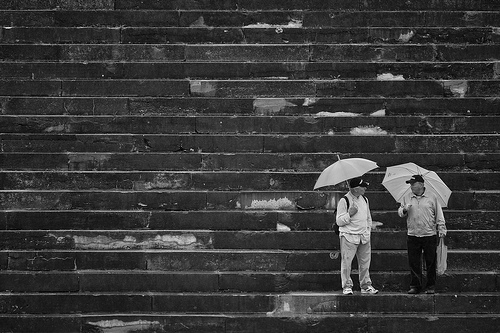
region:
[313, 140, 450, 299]
two old people with umbrellas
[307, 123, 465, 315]
two old people with umbrellas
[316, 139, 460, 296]
two men talking on stairs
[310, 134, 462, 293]
two men holding white umbrellas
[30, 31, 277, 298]
long concrete staircase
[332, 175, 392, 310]
man wearing tennis shoes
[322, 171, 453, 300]
two men wearing ball caps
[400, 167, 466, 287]
man is carrying grocery sack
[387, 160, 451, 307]
man wearing black pants and jacket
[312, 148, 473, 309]
men holding matching white umbrellas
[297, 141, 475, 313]
two men talking in the rain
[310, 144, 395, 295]
man wearing a backpack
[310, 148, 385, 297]
Man with blue jeans holdin umbrella.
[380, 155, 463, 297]
Man holding bag holding umbrella.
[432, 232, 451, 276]
Shopping bag in left hand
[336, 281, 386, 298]
White sneakers on man to left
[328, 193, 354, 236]
backpack on man to the left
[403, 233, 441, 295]
black pants on man to the right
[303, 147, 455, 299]
Men talking to each other with umbrellas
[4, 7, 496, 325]
Weathered flight of long steps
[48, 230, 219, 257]
Worn down step that lost some paint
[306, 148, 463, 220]
Lightly colored umbrellas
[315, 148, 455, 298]
two men holding umbrellas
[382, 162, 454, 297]
man holding white umbrella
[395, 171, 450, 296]
man holding plastic bag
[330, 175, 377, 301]
man wearing a black hat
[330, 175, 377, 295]
man wearing black backpack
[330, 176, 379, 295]
man wearing white shirt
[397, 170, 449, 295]
man wearing black pants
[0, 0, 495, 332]
two men on a large staircase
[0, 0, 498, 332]
large dark stone staircase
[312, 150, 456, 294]
two men talking to each other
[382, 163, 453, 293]
man with the black pants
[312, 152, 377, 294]
man with the light colored pants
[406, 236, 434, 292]
a pair of black pants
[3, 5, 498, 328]
large stone steps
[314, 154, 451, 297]
two men holding umbellas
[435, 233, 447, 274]
a plastic shopping bag in the man's hand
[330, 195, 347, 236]
a black backpack on the man's shoulder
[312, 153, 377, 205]
the left man's umbrella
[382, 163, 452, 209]
the right man's umbrella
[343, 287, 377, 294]
a pair of white tennis shoes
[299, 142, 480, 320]
two people near wall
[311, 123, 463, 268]
people are holding umbrellas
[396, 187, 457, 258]
man has grey shirt